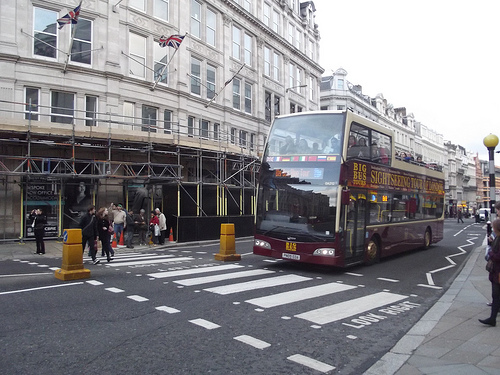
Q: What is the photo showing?
A: It is showing a street.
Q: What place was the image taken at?
A: It was taken at the street.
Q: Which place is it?
A: It is a street.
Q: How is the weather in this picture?
A: It is overcast.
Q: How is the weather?
A: It is overcast.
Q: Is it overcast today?
A: Yes, it is overcast.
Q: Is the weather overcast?
A: Yes, it is overcast.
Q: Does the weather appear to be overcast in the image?
A: Yes, it is overcast.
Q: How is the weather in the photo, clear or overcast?
A: It is overcast.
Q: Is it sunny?
A: No, it is overcast.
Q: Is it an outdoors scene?
A: Yes, it is outdoors.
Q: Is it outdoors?
A: Yes, it is outdoors.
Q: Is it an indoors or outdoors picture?
A: It is outdoors.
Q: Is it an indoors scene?
A: No, it is outdoors.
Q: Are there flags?
A: Yes, there is a flag.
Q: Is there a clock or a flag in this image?
A: Yes, there is a flag.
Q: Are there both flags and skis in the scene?
A: No, there is a flag but no skis.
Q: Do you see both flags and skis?
A: No, there is a flag but no skis.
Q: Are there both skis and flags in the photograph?
A: No, there is a flag but no skis.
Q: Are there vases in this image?
A: No, there are no vases.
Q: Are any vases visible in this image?
A: No, there are no vases.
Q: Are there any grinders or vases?
A: No, there are no vases or grinders.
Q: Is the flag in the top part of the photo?
A: Yes, the flag is in the top of the image.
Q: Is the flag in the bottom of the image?
A: No, the flag is in the top of the image.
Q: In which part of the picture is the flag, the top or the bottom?
A: The flag is in the top of the image.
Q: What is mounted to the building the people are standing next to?
A: The flag is mounted to the building.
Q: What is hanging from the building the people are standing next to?
A: The flag is hanging from the building.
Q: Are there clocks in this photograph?
A: No, there are no clocks.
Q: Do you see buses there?
A: Yes, there is a bus.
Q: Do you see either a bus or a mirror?
A: Yes, there is a bus.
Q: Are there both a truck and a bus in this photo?
A: No, there is a bus but no trucks.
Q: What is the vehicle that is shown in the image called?
A: The vehicle is a bus.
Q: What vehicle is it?
A: The vehicle is a bus.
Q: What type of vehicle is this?
A: This is a bus.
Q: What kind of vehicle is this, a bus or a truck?
A: This is a bus.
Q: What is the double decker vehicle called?
A: The vehicle is a bus.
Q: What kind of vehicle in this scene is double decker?
A: The vehicle is a bus.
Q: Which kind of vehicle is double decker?
A: The vehicle is a bus.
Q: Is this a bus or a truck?
A: This is a bus.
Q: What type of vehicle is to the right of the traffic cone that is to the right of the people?
A: The vehicle is a bus.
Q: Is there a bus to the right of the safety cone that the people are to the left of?
A: Yes, there is a bus to the right of the cone.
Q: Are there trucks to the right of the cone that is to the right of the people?
A: No, there is a bus to the right of the cone.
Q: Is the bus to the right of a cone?
A: Yes, the bus is to the right of a cone.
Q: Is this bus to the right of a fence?
A: No, the bus is to the right of a cone.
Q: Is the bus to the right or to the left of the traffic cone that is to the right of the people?
A: The bus is to the right of the traffic cone.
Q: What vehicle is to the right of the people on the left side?
A: The vehicle is a bus.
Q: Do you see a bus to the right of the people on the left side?
A: Yes, there is a bus to the right of the people.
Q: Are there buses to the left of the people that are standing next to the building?
A: No, the bus is to the right of the people.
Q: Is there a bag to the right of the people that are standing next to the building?
A: No, there is a bus to the right of the people.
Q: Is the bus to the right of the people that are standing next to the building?
A: Yes, the bus is to the right of the people.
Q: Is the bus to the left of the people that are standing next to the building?
A: No, the bus is to the right of the people.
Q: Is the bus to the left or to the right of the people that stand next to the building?
A: The bus is to the right of the people.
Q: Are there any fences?
A: No, there are no fences.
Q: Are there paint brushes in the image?
A: No, there are no paint brushes.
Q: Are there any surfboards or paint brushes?
A: No, there are no paint brushes or surfboards.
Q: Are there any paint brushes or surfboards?
A: No, there are no paint brushes or surfboards.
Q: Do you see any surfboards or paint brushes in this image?
A: No, there are no paint brushes or surfboards.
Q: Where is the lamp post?
A: The lamp post is on the sidewalk.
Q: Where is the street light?
A: The lamp post is on the sidewalk.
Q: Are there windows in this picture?
A: Yes, there is a window.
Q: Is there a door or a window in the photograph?
A: Yes, there is a window.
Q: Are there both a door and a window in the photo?
A: Yes, there are both a window and a door.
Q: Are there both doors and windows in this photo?
A: Yes, there are both a window and a door.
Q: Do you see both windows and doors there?
A: Yes, there are both a window and a door.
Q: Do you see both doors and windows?
A: Yes, there are both a window and a door.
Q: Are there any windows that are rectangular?
A: Yes, there is a rectangular window.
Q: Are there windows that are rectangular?
A: Yes, there is a window that is rectangular.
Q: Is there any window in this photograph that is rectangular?
A: Yes, there is a window that is rectangular.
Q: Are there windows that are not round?
A: Yes, there is a rectangular window.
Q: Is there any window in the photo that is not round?
A: Yes, there is a rectangular window.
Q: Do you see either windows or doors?
A: Yes, there is a window.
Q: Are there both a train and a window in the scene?
A: No, there is a window but no trains.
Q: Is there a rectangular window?
A: Yes, there is a rectangular window.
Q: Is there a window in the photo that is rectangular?
A: Yes, there is a window that is rectangular.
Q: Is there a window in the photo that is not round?
A: Yes, there is a rectangular window.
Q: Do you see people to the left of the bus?
A: Yes, there are people to the left of the bus.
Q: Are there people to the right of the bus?
A: No, the people are to the left of the bus.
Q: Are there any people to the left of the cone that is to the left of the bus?
A: Yes, there are people to the left of the traffic cone.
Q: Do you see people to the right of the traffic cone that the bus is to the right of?
A: No, the people are to the left of the safety cone.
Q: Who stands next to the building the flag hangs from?
A: The people stand next to the building.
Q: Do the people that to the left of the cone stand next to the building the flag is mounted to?
A: Yes, the people stand next to the building.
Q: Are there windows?
A: Yes, there is a window.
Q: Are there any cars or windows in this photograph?
A: Yes, there is a window.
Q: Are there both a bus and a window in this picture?
A: Yes, there are both a window and a bus.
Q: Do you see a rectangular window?
A: Yes, there is a rectangular window.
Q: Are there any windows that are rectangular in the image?
A: Yes, there is a rectangular window.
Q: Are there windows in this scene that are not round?
A: Yes, there is a rectangular window.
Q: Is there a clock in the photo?
A: No, there are no clocks.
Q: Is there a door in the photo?
A: Yes, there is a door.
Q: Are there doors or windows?
A: Yes, there is a door.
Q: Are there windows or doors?
A: Yes, there is a door.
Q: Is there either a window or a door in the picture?
A: Yes, there is a door.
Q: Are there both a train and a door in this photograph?
A: No, there is a door but no trains.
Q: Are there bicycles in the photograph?
A: No, there are no bicycles.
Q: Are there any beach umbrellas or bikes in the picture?
A: No, there are no bikes or beach umbrellas.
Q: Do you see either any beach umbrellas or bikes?
A: No, there are no bikes or beach umbrellas.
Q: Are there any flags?
A: Yes, there is a flag.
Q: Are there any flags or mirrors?
A: Yes, there is a flag.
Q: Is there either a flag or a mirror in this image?
A: Yes, there is a flag.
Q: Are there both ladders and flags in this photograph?
A: No, there is a flag but no ladders.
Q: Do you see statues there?
A: No, there are no statues.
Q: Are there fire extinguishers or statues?
A: No, there are no statues or fire extinguishers.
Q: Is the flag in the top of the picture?
A: Yes, the flag is in the top of the image.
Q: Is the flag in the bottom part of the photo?
A: No, the flag is in the top of the image.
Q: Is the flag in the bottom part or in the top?
A: The flag is in the top of the image.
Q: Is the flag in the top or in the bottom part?
A: The flag is in the top of the image.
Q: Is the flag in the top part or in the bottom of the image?
A: The flag is in the top of the image.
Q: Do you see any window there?
A: Yes, there is a window.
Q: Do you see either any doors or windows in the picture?
A: Yes, there is a window.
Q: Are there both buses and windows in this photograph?
A: Yes, there are both a window and a bus.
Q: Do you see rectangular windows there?
A: Yes, there is a rectangular window.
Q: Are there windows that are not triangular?
A: Yes, there is a rectangular window.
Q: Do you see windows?
A: Yes, there is a window.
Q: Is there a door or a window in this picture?
A: Yes, there is a window.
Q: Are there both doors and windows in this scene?
A: Yes, there are both a window and a door.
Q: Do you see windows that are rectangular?
A: Yes, there is a rectangular window.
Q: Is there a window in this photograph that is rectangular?
A: Yes, there is a window that is rectangular.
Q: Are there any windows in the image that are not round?
A: Yes, there is a rectangular window.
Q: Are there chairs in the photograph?
A: No, there are no chairs.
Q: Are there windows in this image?
A: Yes, there is a window.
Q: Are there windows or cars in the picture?
A: Yes, there is a window.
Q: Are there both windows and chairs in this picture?
A: No, there is a window but no chairs.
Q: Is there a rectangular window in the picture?
A: Yes, there is a rectangular window.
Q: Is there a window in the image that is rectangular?
A: Yes, there is a window that is rectangular.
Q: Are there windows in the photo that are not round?
A: Yes, there is a rectangular window.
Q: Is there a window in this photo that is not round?
A: Yes, there is a rectangular window.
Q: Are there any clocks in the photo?
A: No, there are no clocks.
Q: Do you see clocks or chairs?
A: No, there are no clocks or chairs.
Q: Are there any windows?
A: Yes, there is a window.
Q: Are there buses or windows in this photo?
A: Yes, there is a window.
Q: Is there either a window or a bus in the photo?
A: Yes, there is a window.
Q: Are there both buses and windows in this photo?
A: Yes, there are both a window and a bus.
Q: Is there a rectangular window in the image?
A: Yes, there is a rectangular window.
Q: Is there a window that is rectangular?
A: Yes, there is a window that is rectangular.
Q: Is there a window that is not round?
A: Yes, there is a rectangular window.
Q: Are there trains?
A: No, there are no trains.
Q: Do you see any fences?
A: No, there are no fences.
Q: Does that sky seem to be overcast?
A: Yes, the sky is overcast.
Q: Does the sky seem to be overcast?
A: Yes, the sky is overcast.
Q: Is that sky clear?
A: No, the sky is overcast.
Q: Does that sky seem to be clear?
A: No, the sky is overcast.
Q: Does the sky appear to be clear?
A: No, the sky is overcast.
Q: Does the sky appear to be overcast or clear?
A: The sky is overcast.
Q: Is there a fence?
A: No, there are no fences.